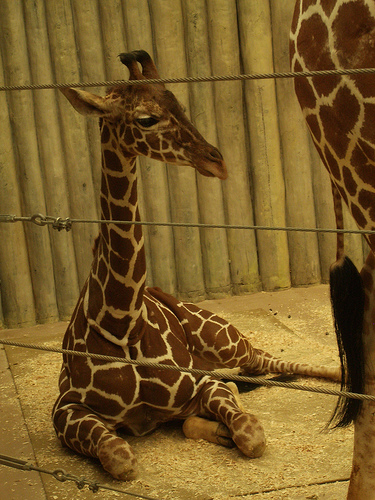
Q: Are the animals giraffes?
A: Yes, all the animals are giraffes.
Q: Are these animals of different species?
A: No, all the animals are giraffes.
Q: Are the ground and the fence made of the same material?
A: No, the ground is made of cement and the fence is made of wood.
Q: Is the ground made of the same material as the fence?
A: No, the ground is made of cement and the fence is made of wood.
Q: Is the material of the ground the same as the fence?
A: No, the ground is made of cement and the fence is made of wood.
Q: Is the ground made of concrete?
A: Yes, the ground is made of concrete.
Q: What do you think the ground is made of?
A: The ground is made of cement.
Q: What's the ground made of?
A: The ground is made of concrete.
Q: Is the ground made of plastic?
A: No, the ground is made of cement.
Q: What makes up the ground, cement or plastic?
A: The ground is made of cement.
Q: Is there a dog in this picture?
A: No, there are no dogs.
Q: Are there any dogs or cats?
A: No, there are no dogs or cats.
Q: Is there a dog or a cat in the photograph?
A: No, there are no dogs or cats.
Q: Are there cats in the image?
A: No, there are no cats.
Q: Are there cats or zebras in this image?
A: No, there are no cats or zebras.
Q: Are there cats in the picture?
A: No, there are no cats.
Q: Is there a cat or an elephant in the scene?
A: No, there are no cats or elephants.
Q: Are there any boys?
A: No, there are no boys.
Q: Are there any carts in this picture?
A: No, there are no carts.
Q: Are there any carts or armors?
A: No, there are no carts or armors.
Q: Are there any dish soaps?
A: No, there are no dish soaps.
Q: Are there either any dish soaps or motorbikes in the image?
A: No, there are no dish soaps or motorbikes.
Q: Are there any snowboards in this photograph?
A: No, there are no snowboards.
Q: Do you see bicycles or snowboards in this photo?
A: No, there are no snowboards or bicycles.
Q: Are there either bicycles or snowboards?
A: No, there are no snowboards or bicycles.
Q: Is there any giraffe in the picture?
A: Yes, there is a giraffe.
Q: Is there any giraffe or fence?
A: Yes, there is a giraffe.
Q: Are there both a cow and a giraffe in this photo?
A: No, there is a giraffe but no cows.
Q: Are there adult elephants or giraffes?
A: Yes, there is an adult giraffe.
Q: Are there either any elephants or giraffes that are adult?
A: Yes, the giraffe is adult.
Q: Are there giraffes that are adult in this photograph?
A: Yes, there is an adult giraffe.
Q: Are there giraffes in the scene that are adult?
A: Yes, there is an adult giraffe.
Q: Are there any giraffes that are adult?
A: Yes, there is a giraffe that is adult.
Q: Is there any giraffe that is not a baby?
A: Yes, there is a adult giraffe.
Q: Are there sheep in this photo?
A: No, there are no sheep.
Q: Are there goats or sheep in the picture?
A: No, there are no sheep or goats.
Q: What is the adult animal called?
A: The animal is a giraffe.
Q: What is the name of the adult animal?
A: The animal is a giraffe.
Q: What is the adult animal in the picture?
A: The animal is a giraffe.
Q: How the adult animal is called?
A: The animal is a giraffe.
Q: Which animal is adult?
A: The animal is a giraffe.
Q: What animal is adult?
A: The animal is a giraffe.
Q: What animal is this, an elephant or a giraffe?
A: This is a giraffe.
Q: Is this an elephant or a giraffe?
A: This is a giraffe.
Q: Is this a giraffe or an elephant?
A: This is a giraffe.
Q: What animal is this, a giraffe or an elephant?
A: This is a giraffe.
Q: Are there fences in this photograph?
A: Yes, there is a fence.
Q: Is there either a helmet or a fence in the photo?
A: Yes, there is a fence.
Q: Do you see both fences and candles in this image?
A: No, there is a fence but no candles.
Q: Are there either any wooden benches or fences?
A: Yes, there is a wood fence.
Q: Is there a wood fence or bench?
A: Yes, there is a wood fence.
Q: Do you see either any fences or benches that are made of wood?
A: Yes, the fence is made of wood.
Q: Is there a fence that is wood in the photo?
A: Yes, there is a wood fence.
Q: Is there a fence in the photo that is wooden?
A: Yes, there is a fence that is wooden.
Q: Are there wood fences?
A: Yes, there is a fence that is made of wood.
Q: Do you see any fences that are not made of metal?
A: Yes, there is a fence that is made of wood.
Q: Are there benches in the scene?
A: No, there are no benches.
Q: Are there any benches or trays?
A: No, there are no benches or trays.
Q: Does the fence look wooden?
A: Yes, the fence is wooden.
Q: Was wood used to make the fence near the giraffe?
A: Yes, the fence is made of wood.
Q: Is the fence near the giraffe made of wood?
A: Yes, the fence is made of wood.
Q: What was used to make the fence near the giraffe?
A: The fence is made of wood.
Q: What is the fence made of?
A: The fence is made of wood.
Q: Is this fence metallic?
A: No, the fence is wooden.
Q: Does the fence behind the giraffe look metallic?
A: No, the fence is wooden.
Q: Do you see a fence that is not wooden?
A: No, there is a fence but it is wooden.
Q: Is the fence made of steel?
A: No, the fence is made of wood.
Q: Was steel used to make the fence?
A: No, the fence is made of wood.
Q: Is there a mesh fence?
A: No, there is a fence but it is made of wood.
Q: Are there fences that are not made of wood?
A: No, there is a fence but it is made of wood.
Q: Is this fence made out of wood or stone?
A: The fence is made of wood.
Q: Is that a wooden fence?
A: Yes, that is a wooden fence.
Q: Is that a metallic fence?
A: No, that is a wooden fence.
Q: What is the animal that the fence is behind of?
A: The animal is a giraffe.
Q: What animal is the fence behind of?
A: The fence is behind the giraffe.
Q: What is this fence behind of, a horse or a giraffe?
A: The fence is behind a giraffe.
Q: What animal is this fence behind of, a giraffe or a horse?
A: The fence is behind a giraffe.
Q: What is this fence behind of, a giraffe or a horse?
A: The fence is behind a giraffe.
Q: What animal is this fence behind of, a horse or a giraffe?
A: The fence is behind a giraffe.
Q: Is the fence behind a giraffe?
A: Yes, the fence is behind a giraffe.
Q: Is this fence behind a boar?
A: No, the fence is behind a giraffe.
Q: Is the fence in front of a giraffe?
A: No, the fence is behind a giraffe.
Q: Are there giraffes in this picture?
A: Yes, there is a giraffe.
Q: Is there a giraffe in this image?
A: Yes, there is a giraffe.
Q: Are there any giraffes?
A: Yes, there is a giraffe.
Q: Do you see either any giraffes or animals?
A: Yes, there is a giraffe.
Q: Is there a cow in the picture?
A: No, there are no cows.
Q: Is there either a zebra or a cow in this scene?
A: No, there are no cows or zebras.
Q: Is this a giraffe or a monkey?
A: This is a giraffe.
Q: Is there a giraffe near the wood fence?
A: Yes, there is a giraffe near the fence.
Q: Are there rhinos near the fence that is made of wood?
A: No, there is a giraffe near the fence.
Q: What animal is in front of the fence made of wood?
A: The animal is a giraffe.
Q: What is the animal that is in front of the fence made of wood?
A: The animal is a giraffe.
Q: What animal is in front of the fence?
A: The animal is a giraffe.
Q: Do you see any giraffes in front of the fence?
A: Yes, there is a giraffe in front of the fence.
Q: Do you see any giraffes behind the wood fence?
A: No, the giraffe is in front of the fence.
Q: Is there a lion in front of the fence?
A: No, there is a giraffe in front of the fence.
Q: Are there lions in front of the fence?
A: No, there is a giraffe in front of the fence.